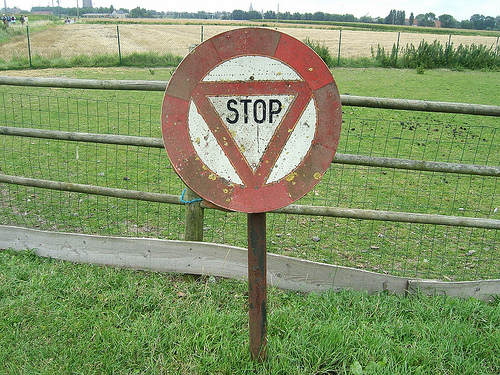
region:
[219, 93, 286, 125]
black letters on sign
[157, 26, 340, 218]
red and white metal sign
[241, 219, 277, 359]
rusted metal sign post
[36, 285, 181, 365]
lush grass on ground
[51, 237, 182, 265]
wooden board on fence base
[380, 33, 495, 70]
row of bushes beside fence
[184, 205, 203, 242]
wooden fence post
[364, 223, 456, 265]
black metal fencing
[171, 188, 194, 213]
blue rope on fence post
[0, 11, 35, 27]
group of people walking beside field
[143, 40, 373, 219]
a rusted stop sign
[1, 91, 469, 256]
a wire and wooden fence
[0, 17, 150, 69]
metal fence post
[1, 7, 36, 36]
several people standing in a field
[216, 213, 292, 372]
rusted metal pole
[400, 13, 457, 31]
a building with a red roof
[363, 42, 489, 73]
tall green weeds next to a fence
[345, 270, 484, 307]
two wooden boards nailed together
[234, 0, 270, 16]
a tall building with a steeple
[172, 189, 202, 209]
a blue wire around a fence post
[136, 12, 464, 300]
the signboard is circle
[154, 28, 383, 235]
an old fashioned stop sign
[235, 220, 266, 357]
a rusty black pole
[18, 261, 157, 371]
green grass under the fence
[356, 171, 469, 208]
wire mesh on the fence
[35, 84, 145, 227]
wooden poles on the fence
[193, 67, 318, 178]
a red and white triangle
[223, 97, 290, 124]
black letters on the sign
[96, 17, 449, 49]
a large field behind the sign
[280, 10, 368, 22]
a line of trees in the background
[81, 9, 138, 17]
a brick house across from the field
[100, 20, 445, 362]
A foreign stop sign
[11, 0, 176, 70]
Dry farm land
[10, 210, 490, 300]
An uneven wood based fence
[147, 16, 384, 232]
Warning ahead of you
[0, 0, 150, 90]
Working the fields in the fall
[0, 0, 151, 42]
Harvesting crops from land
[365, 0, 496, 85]
Baby Cypress trees planted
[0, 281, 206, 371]
Dry green grass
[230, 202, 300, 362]
Rusty post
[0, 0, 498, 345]
A fall day on the farm